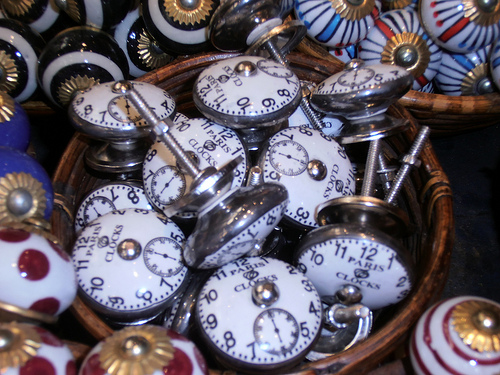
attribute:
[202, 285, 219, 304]
10 — black, small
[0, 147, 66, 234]
ball — blue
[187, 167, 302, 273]
knob — black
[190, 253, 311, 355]
knob — black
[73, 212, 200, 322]
knob — black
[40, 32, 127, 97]
knob — black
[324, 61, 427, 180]
knob — black, white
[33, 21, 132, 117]
ball — black, white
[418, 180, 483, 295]
basket — brown, striped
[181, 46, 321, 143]
clock — black, white, miniature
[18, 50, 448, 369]
items — red, white, polka-dot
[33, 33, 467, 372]
bowl — wicker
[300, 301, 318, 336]
number — black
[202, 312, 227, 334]
number — black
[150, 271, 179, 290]
number — black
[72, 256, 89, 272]
number — black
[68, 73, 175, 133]
clock — small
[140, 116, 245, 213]
clock — small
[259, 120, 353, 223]
clock — small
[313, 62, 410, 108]
clock — small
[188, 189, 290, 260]
clock — small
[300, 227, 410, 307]
clock — small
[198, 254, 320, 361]
clock — small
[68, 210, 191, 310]
clock — small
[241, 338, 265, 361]
seven — black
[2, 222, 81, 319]
polka dots — red, white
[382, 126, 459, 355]
basket — brown, wicker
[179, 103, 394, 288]
knobs — decorative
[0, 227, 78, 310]
ball — white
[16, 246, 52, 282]
dot — red